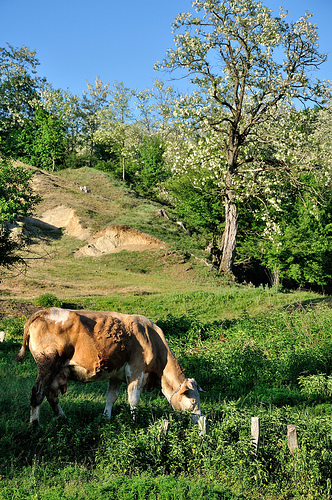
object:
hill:
[45, 158, 165, 279]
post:
[249, 413, 261, 459]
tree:
[149, 0, 332, 272]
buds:
[266, 28, 272, 36]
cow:
[17, 305, 227, 449]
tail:
[15, 324, 29, 363]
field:
[194, 274, 327, 378]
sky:
[0, 0, 331, 112]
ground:
[0, 159, 331, 497]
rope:
[168, 376, 188, 405]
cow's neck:
[157, 355, 186, 400]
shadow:
[171, 353, 323, 409]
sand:
[75, 228, 152, 262]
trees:
[0, 139, 39, 264]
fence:
[159, 415, 317, 463]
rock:
[78, 185, 91, 194]